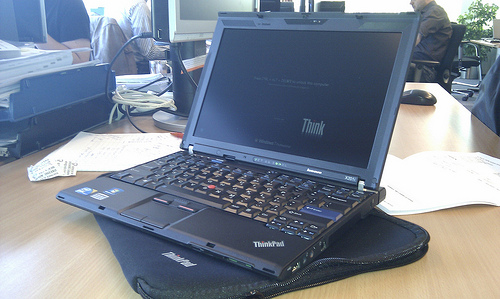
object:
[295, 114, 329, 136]
words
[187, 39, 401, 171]
screen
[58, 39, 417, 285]
laptop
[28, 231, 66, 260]
table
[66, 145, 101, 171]
paper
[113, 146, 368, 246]
keyboard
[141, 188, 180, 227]
trackpad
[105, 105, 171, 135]
cords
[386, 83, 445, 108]
mouse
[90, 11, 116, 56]
person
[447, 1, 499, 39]
tree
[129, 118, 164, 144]
papers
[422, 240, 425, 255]
desk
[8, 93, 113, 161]
bag